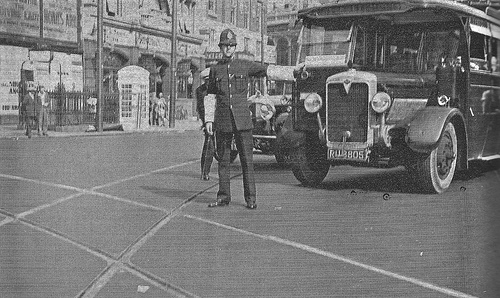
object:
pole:
[89, 3, 110, 132]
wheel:
[408, 111, 462, 196]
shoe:
[241, 173, 273, 214]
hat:
[217, 29, 237, 46]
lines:
[57, 188, 476, 297]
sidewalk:
[5, 109, 179, 150]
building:
[1, 0, 268, 137]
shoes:
[209, 184, 292, 226]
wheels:
[286, 127, 331, 188]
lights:
[303, 91, 324, 114]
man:
[204, 28, 304, 208]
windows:
[348, 11, 473, 73]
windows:
[467, 29, 490, 63]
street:
[49, 187, 388, 275]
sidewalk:
[36, 116, 206, 139]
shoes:
[211, 185, 311, 235]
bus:
[280, 0, 500, 190]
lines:
[0, 184, 155, 298]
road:
[0, 240, 500, 298]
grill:
[322, 71, 382, 156]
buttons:
[227, 62, 234, 112]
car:
[214, 62, 293, 166]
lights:
[368, 90, 391, 114]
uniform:
[194, 53, 292, 201]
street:
[5, 145, 178, 289]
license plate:
[327, 146, 372, 161]